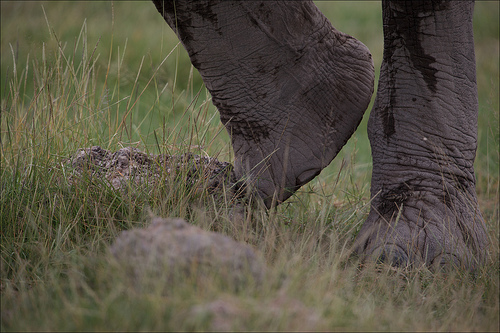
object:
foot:
[334, 184, 493, 278]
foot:
[226, 31, 378, 212]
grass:
[0, 0, 500, 333]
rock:
[63, 143, 237, 208]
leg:
[364, 0, 481, 206]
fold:
[420, 130, 466, 146]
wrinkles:
[280, 140, 309, 163]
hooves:
[228, 29, 379, 211]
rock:
[103, 215, 270, 288]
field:
[0, 0, 500, 333]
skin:
[368, 41, 481, 214]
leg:
[150, 0, 327, 133]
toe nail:
[365, 243, 411, 269]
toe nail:
[430, 252, 462, 271]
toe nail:
[245, 185, 278, 212]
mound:
[50, 140, 245, 226]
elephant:
[148, 0, 496, 277]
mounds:
[94, 218, 275, 296]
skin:
[149, 0, 377, 212]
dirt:
[100, 210, 274, 290]